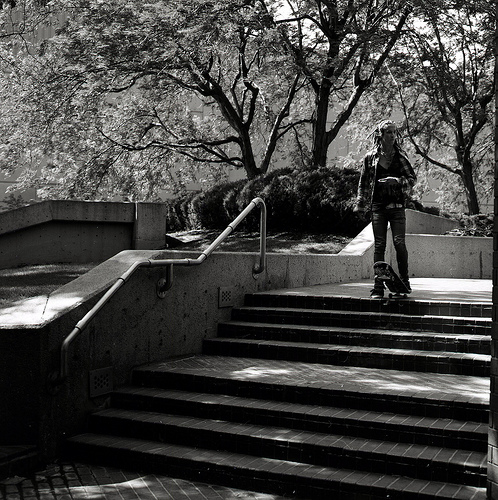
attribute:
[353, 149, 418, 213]
shirt — plaid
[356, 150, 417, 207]
shirt — squared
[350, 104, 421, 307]
person — standing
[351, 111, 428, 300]
person — standing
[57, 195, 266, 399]
rail — metal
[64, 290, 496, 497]
stairs — sloping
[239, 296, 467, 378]
stairs — bricks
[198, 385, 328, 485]
floor — tiled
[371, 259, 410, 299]
skateboard — tilted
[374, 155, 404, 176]
shirt — v cut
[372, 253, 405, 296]
skater — black